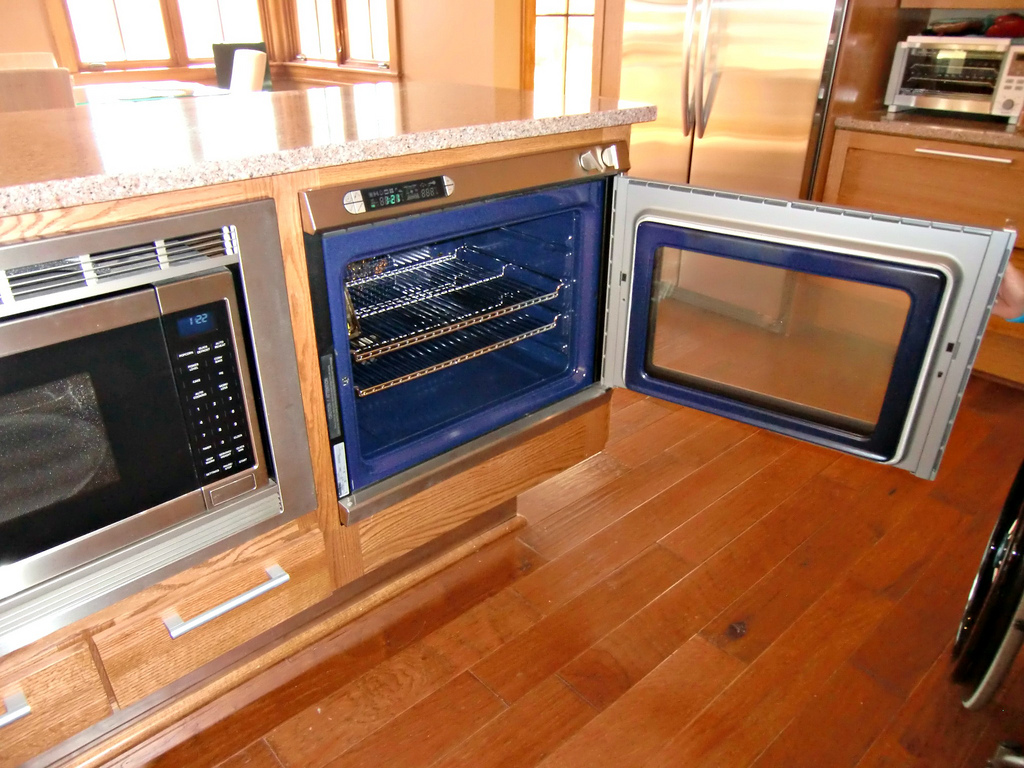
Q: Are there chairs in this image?
A: Yes, there is a chair.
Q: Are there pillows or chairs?
A: Yes, there is a chair.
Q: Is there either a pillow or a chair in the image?
A: Yes, there is a chair.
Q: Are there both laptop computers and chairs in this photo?
A: No, there is a chair but no laptops.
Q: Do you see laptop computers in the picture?
A: No, there are no laptop computers.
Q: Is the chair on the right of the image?
A: No, the chair is on the left of the image.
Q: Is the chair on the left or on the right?
A: The chair is on the left of the image.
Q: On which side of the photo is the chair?
A: The chair is on the left of the image.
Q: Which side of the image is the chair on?
A: The chair is on the left of the image.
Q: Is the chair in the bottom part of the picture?
A: No, the chair is in the top of the image.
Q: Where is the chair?
A: The chair is at the dining table.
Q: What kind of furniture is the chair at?
A: The chair is at the dining table.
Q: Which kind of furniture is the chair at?
A: The chair is at the dining table.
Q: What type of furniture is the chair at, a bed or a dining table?
A: The chair is at a dining table.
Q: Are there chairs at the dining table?
A: Yes, there is a chair at the dining table.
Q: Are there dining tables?
A: Yes, there is a dining table.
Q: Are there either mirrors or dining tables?
A: Yes, there is a dining table.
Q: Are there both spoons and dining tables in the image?
A: No, there is a dining table but no spoons.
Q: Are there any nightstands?
A: No, there are no nightstands.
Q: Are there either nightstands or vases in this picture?
A: No, there are no nightstands or vases.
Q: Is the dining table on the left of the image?
A: Yes, the dining table is on the left of the image.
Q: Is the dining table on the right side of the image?
A: No, the dining table is on the left of the image.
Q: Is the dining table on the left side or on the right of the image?
A: The dining table is on the left of the image.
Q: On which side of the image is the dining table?
A: The dining table is on the left of the image.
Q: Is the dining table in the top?
A: Yes, the dining table is in the top of the image.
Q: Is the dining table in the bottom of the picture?
A: No, the dining table is in the top of the image.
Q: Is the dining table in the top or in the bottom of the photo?
A: The dining table is in the top of the image.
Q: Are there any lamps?
A: No, there are no lamps.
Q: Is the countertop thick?
A: Yes, the countertop is thick.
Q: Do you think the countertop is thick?
A: Yes, the countertop is thick.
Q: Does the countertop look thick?
A: Yes, the countertop is thick.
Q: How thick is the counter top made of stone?
A: The counter top is thick.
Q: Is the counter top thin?
A: No, the counter top is thick.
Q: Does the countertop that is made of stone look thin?
A: No, the countertop is thick.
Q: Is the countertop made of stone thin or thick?
A: The counter top is thick.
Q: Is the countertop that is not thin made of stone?
A: Yes, the countertop is made of stone.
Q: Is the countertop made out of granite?
A: No, the countertop is made of stone.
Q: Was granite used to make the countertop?
A: No, the countertop is made of stone.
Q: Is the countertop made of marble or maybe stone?
A: The countertop is made of stone.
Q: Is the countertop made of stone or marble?
A: The countertop is made of stone.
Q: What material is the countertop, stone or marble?
A: The countertop is made of stone.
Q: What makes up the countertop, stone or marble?
A: The countertop is made of stone.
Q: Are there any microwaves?
A: Yes, there is a microwave.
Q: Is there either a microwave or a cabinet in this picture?
A: Yes, there is a microwave.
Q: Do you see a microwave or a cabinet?
A: Yes, there is a microwave.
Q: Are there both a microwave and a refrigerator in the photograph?
A: Yes, there are both a microwave and a refrigerator.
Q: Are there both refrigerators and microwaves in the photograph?
A: Yes, there are both a microwave and a refrigerator.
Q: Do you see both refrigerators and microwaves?
A: Yes, there are both a microwave and a refrigerator.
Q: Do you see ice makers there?
A: No, there are no ice makers.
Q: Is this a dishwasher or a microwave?
A: This is a microwave.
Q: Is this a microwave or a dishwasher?
A: This is a microwave.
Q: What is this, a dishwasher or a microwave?
A: This is a microwave.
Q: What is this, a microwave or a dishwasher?
A: This is a microwave.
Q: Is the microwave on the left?
A: Yes, the microwave is on the left of the image.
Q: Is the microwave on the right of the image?
A: No, the microwave is on the left of the image.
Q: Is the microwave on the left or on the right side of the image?
A: The microwave is on the left of the image.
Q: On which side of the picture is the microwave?
A: The microwave is on the left of the image.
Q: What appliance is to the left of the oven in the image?
A: The appliance is a microwave.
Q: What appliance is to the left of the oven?
A: The appliance is a microwave.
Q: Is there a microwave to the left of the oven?
A: Yes, there is a microwave to the left of the oven.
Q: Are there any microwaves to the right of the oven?
A: No, the microwave is to the left of the oven.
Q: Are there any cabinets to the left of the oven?
A: No, there is a microwave to the left of the oven.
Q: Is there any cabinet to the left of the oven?
A: No, there is a microwave to the left of the oven.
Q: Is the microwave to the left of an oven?
A: Yes, the microwave is to the left of an oven.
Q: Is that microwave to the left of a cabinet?
A: No, the microwave is to the left of an oven.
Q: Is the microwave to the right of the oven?
A: No, the microwave is to the left of the oven.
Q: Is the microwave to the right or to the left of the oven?
A: The microwave is to the left of the oven.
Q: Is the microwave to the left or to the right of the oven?
A: The microwave is to the left of the oven.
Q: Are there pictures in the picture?
A: No, there are no pictures.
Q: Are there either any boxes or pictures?
A: No, there are no pictures or boxes.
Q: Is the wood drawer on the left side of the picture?
A: Yes, the drawer is on the left of the image.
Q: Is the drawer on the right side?
A: No, the drawer is on the left of the image.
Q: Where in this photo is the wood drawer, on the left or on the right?
A: The drawer is on the left of the image.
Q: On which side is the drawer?
A: The drawer is on the left of the image.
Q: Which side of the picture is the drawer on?
A: The drawer is on the left of the image.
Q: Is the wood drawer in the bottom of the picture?
A: Yes, the drawer is in the bottom of the image.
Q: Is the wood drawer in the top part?
A: No, the drawer is in the bottom of the image.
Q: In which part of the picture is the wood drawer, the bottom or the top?
A: The drawer is in the bottom of the image.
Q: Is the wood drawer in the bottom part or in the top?
A: The drawer is in the bottom of the image.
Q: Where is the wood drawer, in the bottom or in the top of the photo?
A: The drawer is in the bottom of the image.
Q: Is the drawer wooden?
A: Yes, the drawer is wooden.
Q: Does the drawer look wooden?
A: Yes, the drawer is wooden.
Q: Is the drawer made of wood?
A: Yes, the drawer is made of wood.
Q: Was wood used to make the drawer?
A: Yes, the drawer is made of wood.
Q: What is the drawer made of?
A: The drawer is made of wood.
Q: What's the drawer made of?
A: The drawer is made of wood.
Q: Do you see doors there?
A: Yes, there is a door.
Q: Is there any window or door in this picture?
A: Yes, there is a door.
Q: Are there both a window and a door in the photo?
A: Yes, there are both a door and a window.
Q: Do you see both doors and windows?
A: Yes, there are both a door and a window.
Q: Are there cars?
A: No, there are no cars.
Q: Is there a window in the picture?
A: Yes, there are windows.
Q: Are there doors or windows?
A: Yes, there are windows.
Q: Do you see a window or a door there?
A: Yes, there are windows.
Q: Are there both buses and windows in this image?
A: No, there are windows but no buses.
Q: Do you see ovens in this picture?
A: Yes, there is an oven.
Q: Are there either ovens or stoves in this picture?
A: Yes, there is an oven.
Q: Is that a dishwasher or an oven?
A: That is an oven.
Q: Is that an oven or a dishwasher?
A: That is an oven.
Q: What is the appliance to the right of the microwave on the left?
A: The appliance is an oven.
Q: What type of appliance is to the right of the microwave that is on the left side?
A: The appliance is an oven.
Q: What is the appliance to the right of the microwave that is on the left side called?
A: The appliance is an oven.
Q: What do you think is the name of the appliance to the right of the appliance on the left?
A: The appliance is an oven.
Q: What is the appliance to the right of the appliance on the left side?
A: The appliance is an oven.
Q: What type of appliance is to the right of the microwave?
A: The appliance is an oven.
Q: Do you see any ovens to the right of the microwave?
A: Yes, there is an oven to the right of the microwave.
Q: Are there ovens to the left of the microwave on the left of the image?
A: No, the oven is to the right of the microwave.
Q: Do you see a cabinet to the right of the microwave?
A: No, there is an oven to the right of the microwave.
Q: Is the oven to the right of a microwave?
A: Yes, the oven is to the right of a microwave.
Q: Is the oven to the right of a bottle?
A: No, the oven is to the right of a microwave.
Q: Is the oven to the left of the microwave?
A: No, the oven is to the right of the microwave.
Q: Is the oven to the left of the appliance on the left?
A: No, the oven is to the right of the microwave.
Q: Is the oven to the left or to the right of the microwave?
A: The oven is to the right of the microwave.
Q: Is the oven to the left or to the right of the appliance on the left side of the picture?
A: The oven is to the right of the microwave.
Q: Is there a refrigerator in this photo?
A: Yes, there is a refrigerator.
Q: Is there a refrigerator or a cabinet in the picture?
A: Yes, there is a refrigerator.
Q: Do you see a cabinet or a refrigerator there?
A: Yes, there is a refrigerator.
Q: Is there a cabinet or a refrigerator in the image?
A: Yes, there is a refrigerator.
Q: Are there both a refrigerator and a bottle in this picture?
A: No, there is a refrigerator but no bottles.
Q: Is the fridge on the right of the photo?
A: Yes, the fridge is on the right of the image.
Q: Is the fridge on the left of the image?
A: No, the fridge is on the right of the image.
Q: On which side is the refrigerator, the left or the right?
A: The refrigerator is on the right of the image.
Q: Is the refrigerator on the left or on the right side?
A: The refrigerator is on the right of the image.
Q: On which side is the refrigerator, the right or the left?
A: The refrigerator is on the right of the image.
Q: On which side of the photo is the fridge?
A: The fridge is on the right of the image.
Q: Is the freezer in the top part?
A: Yes, the freezer is in the top of the image.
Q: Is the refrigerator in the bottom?
A: No, the refrigerator is in the top of the image.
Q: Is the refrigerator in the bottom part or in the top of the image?
A: The refrigerator is in the top of the image.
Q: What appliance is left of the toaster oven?
A: The appliance is a refrigerator.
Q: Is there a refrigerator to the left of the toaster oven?
A: Yes, there is a refrigerator to the left of the toaster oven.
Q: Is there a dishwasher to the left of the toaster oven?
A: No, there is a refrigerator to the left of the toaster oven.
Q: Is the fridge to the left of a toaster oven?
A: Yes, the fridge is to the left of a toaster oven.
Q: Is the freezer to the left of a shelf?
A: No, the freezer is to the left of a toaster oven.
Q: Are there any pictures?
A: No, there are no pictures.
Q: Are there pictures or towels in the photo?
A: No, there are no pictures or towels.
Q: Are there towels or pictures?
A: No, there are no pictures or towels.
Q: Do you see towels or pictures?
A: No, there are no pictures or towels.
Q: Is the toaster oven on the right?
A: Yes, the toaster oven is on the right of the image.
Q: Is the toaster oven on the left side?
A: No, the toaster oven is on the right of the image.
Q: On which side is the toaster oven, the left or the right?
A: The toaster oven is on the right of the image.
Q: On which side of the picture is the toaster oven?
A: The toaster oven is on the right of the image.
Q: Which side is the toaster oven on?
A: The toaster oven is on the right of the image.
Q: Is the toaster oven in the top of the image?
A: Yes, the toaster oven is in the top of the image.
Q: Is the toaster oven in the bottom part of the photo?
A: No, the toaster oven is in the top of the image.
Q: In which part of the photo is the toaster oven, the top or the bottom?
A: The toaster oven is in the top of the image.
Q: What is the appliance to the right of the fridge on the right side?
A: The appliance is a toaster oven.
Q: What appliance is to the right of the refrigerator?
A: The appliance is a toaster oven.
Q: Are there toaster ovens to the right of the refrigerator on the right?
A: Yes, there is a toaster oven to the right of the freezer.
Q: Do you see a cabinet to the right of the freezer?
A: No, there is a toaster oven to the right of the freezer.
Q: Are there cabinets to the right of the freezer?
A: No, there is a toaster oven to the right of the freezer.